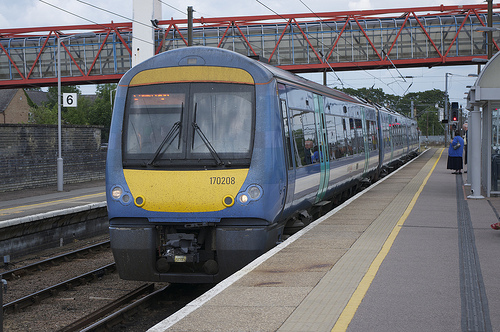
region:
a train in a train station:
[99, 46, 431, 282]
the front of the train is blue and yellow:
[101, 40, 287, 235]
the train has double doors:
[306, 83, 341, 200]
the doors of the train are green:
[308, 88, 340, 203]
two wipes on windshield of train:
[142, 96, 233, 176]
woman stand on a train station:
[436, 124, 468, 182]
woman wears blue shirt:
[442, 121, 472, 181]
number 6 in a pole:
[48, 73, 85, 124]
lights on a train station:
[43, 14, 110, 191]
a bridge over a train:
[0, 0, 494, 82]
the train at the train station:
[97, 18, 394, 273]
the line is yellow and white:
[337, 169, 442, 250]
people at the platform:
[425, 110, 479, 185]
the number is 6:
[50, 86, 77, 111]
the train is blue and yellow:
[89, 43, 281, 274]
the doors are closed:
[293, 85, 428, 212]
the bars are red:
[14, 27, 493, 80]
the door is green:
[290, 67, 350, 222]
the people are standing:
[439, 112, 481, 195]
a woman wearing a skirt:
[433, 144, 468, 168]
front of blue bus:
[112, 51, 284, 247]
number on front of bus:
[199, 170, 235, 187]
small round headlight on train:
[236, 193, 258, 210]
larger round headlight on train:
[246, 182, 266, 199]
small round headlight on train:
[123, 192, 137, 209]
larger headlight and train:
[111, 185, 123, 198]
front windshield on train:
[124, 83, 249, 163]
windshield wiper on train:
[191, 120, 225, 167]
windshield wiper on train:
[151, 122, 190, 167]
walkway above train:
[273, 7, 418, 67]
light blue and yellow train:
[106, 57, 448, 287]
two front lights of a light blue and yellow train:
[92, 171, 277, 231]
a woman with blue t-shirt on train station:
[437, 123, 465, 176]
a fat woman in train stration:
[441, 123, 468, 178]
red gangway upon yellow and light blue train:
[1, 6, 499, 83]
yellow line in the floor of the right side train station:
[322, 133, 450, 328]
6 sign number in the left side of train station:
[60, 85, 80, 100]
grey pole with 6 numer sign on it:
[52, 35, 69, 197]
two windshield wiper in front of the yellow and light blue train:
[153, 116, 227, 168]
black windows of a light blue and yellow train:
[285, 106, 427, 168]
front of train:
[97, 44, 285, 292]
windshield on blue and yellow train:
[120, 74, 261, 266]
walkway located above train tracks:
[0, 3, 472, 102]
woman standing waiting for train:
[350, 101, 481, 194]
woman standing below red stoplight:
[424, 95, 478, 186]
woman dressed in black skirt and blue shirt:
[436, 127, 476, 187]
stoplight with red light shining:
[433, 87, 471, 132]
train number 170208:
[111, 47, 451, 301]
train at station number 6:
[30, 35, 422, 330]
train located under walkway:
[76, 3, 441, 321]